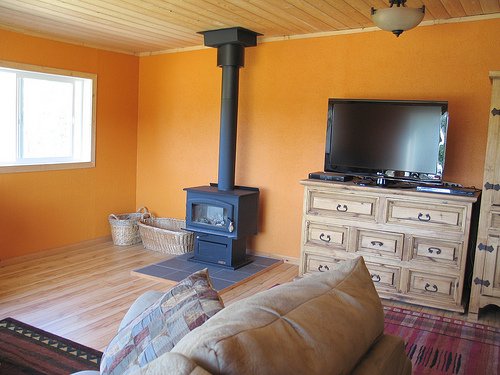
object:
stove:
[182, 183, 261, 269]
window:
[2, 66, 96, 164]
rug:
[382, 305, 499, 374]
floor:
[0, 231, 496, 374]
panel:
[288, 0, 346, 31]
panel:
[125, 0, 230, 29]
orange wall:
[138, 55, 216, 181]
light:
[368, 3, 425, 37]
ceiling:
[0, 0, 498, 57]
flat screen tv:
[328, 98, 446, 182]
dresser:
[298, 180, 466, 312]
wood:
[198, 215, 224, 224]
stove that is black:
[199, 186, 215, 194]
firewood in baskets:
[113, 214, 141, 220]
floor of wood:
[0, 245, 155, 350]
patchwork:
[100, 267, 223, 373]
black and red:
[381, 305, 498, 373]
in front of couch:
[0, 313, 110, 373]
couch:
[97, 257, 410, 372]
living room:
[2, 0, 497, 374]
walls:
[139, 57, 311, 171]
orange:
[252, 40, 483, 101]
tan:
[252, 289, 285, 316]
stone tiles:
[131, 262, 179, 278]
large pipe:
[217, 45, 240, 192]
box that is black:
[309, 172, 353, 182]